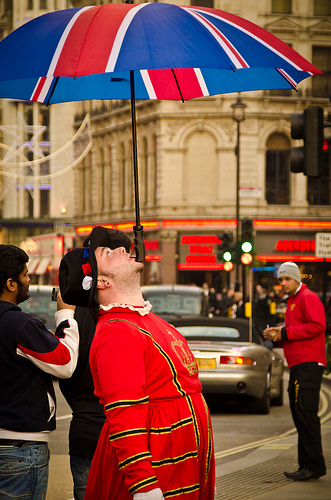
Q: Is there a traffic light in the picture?
A: Yes, there is a traffic light.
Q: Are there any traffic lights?
A: Yes, there is a traffic light.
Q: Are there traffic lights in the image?
A: Yes, there is a traffic light.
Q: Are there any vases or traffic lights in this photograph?
A: Yes, there is a traffic light.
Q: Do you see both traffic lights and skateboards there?
A: No, there is a traffic light but no skateboards.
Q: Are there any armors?
A: No, there are no armors.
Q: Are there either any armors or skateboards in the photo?
A: No, there are no armors or skateboards.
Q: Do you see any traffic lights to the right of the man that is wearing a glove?
A: Yes, there is a traffic light to the right of the man.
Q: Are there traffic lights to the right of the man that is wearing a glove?
A: Yes, there is a traffic light to the right of the man.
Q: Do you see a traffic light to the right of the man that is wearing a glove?
A: Yes, there is a traffic light to the right of the man.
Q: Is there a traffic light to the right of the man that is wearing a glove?
A: Yes, there is a traffic light to the right of the man.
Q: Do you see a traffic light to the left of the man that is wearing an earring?
A: No, the traffic light is to the right of the man.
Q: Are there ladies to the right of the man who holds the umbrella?
A: No, there is a traffic light to the right of the man.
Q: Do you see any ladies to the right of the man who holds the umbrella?
A: No, there is a traffic light to the right of the man.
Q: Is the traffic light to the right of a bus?
A: No, the traffic light is to the right of the man.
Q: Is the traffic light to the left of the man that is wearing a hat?
A: No, the traffic light is to the right of the man.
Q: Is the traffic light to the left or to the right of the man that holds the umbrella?
A: The traffic light is to the right of the man.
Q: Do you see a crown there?
A: Yes, there is a crown.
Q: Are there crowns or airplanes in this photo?
A: Yes, there is a crown.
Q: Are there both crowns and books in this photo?
A: No, there is a crown but no books.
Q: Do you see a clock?
A: No, there are no clocks.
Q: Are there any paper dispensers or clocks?
A: No, there are no clocks or paper dispensers.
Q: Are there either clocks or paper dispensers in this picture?
A: No, there are no clocks or paper dispensers.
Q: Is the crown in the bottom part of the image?
A: Yes, the crown is in the bottom of the image.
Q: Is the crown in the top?
A: No, the crown is in the bottom of the image.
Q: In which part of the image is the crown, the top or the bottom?
A: The crown is in the bottom of the image.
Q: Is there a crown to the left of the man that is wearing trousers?
A: Yes, there is a crown to the left of the man.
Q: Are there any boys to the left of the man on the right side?
A: No, there is a crown to the left of the man.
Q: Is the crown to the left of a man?
A: Yes, the crown is to the left of a man.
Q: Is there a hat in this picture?
A: Yes, there is a hat.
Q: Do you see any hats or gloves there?
A: Yes, there is a hat.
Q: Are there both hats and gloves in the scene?
A: Yes, there are both a hat and gloves.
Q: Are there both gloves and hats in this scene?
A: Yes, there are both a hat and gloves.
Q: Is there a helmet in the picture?
A: No, there are no helmets.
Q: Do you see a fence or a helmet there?
A: No, there are no helmets or fences.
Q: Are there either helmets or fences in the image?
A: No, there are no helmets or fences.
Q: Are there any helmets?
A: No, there are no helmets.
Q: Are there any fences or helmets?
A: No, there are no helmets or fences.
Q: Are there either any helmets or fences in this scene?
A: No, there are no helmets or fences.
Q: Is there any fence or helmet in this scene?
A: No, there are no helmets or fences.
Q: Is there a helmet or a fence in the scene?
A: No, there are no helmets or fences.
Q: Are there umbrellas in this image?
A: Yes, there is an umbrella.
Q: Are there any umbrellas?
A: Yes, there is an umbrella.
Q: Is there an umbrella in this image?
A: Yes, there is an umbrella.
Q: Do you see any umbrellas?
A: Yes, there is an umbrella.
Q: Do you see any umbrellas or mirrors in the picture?
A: Yes, there is an umbrella.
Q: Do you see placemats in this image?
A: No, there are no placemats.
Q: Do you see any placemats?
A: No, there are no placemats.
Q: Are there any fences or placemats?
A: No, there are no placemats or fences.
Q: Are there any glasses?
A: No, there are no glasses.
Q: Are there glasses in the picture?
A: No, there are no glasses.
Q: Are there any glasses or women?
A: No, there are no glasses or women.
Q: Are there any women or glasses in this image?
A: No, there are no glasses or women.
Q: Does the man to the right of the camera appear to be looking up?
A: Yes, the man is looking up.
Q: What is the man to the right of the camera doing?
A: The man is looking up.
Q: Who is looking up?
A: The man is looking up.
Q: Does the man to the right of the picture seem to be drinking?
A: No, the man is looking up.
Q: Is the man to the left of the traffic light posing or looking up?
A: The man is looking up.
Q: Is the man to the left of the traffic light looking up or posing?
A: The man is looking up.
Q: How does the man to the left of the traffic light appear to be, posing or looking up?
A: The man is looking up.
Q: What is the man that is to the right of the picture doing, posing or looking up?
A: The man is looking up.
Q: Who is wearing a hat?
A: The man is wearing a hat.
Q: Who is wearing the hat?
A: The man is wearing a hat.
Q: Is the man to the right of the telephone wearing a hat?
A: Yes, the man is wearing a hat.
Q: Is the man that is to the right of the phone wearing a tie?
A: No, the man is wearing a hat.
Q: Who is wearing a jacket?
A: The man is wearing a jacket.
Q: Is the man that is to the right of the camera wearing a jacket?
A: Yes, the man is wearing a jacket.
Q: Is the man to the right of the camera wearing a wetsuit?
A: No, the man is wearing a jacket.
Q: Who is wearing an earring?
A: The man is wearing an earring.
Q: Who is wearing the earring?
A: The man is wearing an earring.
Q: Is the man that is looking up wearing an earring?
A: Yes, the man is wearing an earring.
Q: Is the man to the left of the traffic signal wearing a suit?
A: No, the man is wearing an earring.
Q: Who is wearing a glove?
A: The man is wearing a glove.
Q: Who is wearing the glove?
A: The man is wearing a glove.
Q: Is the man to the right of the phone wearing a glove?
A: Yes, the man is wearing a glove.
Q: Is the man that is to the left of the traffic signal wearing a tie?
A: No, the man is wearing a glove.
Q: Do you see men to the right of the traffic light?
A: No, the man is to the left of the traffic light.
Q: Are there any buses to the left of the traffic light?
A: No, there is a man to the left of the traffic light.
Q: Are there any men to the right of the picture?
A: Yes, there is a man to the right of the picture.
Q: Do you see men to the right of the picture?
A: Yes, there is a man to the right of the picture.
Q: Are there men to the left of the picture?
A: No, the man is to the right of the picture.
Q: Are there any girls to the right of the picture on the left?
A: No, there is a man to the right of the picture.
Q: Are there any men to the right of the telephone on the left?
A: Yes, there is a man to the right of the phone.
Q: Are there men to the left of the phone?
A: No, the man is to the right of the phone.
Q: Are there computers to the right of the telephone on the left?
A: No, there is a man to the right of the telephone.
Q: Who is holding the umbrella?
A: The man is holding the umbrella.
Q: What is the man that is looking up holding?
A: The man is holding the umbrella.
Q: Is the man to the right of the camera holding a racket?
A: No, the man is holding the umbrella.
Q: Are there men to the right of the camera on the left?
A: Yes, there is a man to the right of the camera.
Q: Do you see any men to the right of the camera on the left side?
A: Yes, there is a man to the right of the camera.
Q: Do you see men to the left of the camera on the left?
A: No, the man is to the right of the camera.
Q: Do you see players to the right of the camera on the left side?
A: No, there is a man to the right of the camera.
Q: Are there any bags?
A: No, there are no bags.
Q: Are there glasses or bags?
A: No, there are no bags or glasses.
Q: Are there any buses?
A: No, there are no buses.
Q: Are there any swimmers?
A: No, there are no swimmers.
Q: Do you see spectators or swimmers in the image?
A: No, there are no swimmers or spectators.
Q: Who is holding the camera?
A: The man is holding the camera.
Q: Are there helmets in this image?
A: No, there are no helmets.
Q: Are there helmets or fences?
A: No, there are no helmets or fences.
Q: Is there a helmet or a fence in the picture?
A: No, there are no helmets or fences.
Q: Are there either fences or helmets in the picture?
A: No, there are no helmets or fences.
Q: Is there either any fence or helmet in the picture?
A: No, there are no helmets or fences.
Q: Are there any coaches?
A: No, there are no coaches.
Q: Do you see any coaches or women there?
A: No, there are no coaches or women.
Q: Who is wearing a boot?
A: The man is wearing a boot.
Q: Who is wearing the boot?
A: The man is wearing a boot.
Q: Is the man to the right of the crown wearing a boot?
A: Yes, the man is wearing a boot.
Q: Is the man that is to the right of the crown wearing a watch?
A: No, the man is wearing a boot.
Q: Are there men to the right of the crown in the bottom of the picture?
A: Yes, there is a man to the right of the crown.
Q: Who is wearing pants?
A: The man is wearing pants.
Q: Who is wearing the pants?
A: The man is wearing pants.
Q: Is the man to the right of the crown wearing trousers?
A: Yes, the man is wearing trousers.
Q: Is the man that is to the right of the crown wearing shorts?
A: No, the man is wearing trousers.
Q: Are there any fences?
A: No, there are no fences.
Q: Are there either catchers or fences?
A: No, there are no fences or catchers.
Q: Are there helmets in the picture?
A: No, there are no helmets.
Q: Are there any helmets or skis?
A: No, there are no helmets or skis.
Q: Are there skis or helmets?
A: No, there are no helmets or skis.